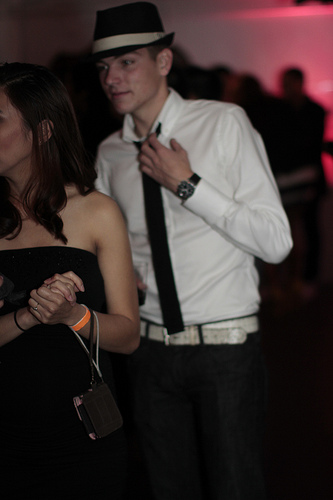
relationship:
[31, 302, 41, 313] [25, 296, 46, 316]
ring on finger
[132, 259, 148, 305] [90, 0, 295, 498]
cup held by boy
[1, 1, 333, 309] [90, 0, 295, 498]
pink light behind boy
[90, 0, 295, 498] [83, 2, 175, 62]
boy wearing a hat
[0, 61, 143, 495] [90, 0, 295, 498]
girl with boy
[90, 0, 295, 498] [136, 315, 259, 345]
boy wearing belt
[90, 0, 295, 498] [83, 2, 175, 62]
boy wearing hat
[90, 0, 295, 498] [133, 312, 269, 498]
boy wearing pants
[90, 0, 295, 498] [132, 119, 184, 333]
boy wearing a tie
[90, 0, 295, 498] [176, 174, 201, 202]
boy wearing a watch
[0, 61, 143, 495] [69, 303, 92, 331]
girl wearing a bracelet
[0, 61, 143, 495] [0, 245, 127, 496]
girl wearing black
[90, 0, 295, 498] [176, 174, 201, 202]
boy has a watch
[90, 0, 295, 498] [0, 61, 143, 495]
boy with girl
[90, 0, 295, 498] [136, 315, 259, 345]
boy wearing a belt